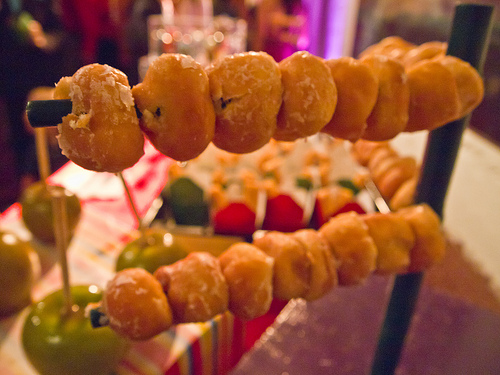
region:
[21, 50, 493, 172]
food on a stick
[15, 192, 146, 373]
green apple on a stick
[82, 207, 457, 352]
donut holes on a pole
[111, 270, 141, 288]
bit of glaze peeling off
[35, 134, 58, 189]
stick sticking out of the apple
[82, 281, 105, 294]
light gleaming on the apple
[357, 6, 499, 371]
skinny black pole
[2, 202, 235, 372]
multicolored striped tablecloth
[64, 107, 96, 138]
bit of donut falling off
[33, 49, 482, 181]
row of eight donut holes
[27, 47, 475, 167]
row of pastries on pole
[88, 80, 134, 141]
glaze coating on pastry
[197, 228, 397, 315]
row of horizontal pastry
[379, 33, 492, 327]
black vertical pole for horizontal poles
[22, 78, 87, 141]
pole end poking through pastry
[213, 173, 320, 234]
red boxes on table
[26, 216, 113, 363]
stick in green apple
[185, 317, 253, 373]
edge of striped tablecloth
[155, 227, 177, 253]
light reflection on apple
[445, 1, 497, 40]
top of black pole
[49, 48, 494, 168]
brown doughnuts on black bar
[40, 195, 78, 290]
brown candy apple stick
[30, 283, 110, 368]
green candied apple sitting on table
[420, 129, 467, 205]
black metal pole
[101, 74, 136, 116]
white glaze on side of doughnut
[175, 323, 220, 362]
striped table cloth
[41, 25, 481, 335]
doughnuts cooling on black pole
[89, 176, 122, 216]
light shining on table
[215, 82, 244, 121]
hole in middle of doughnut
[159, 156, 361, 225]
food sitting on table top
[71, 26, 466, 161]
these are the doughnuts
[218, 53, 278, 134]
the doughnut is brown in color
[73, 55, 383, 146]
the doughnuts are in a line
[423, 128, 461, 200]
this is a pole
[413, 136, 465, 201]
the pole is black in color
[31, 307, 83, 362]
this is an apple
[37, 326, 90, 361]
the apple is green in color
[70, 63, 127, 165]
the doughnut is creamy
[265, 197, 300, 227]
the container is red in color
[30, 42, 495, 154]
a long food skewer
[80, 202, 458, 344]
a long food skewer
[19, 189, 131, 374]
a green candy apple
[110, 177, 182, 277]
a green candy apple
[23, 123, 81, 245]
a green candy apple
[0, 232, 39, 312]
a green candy apple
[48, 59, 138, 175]
a glazed doughnut hole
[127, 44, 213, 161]
a glazed doughnut hole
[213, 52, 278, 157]
a glazed doughnut hole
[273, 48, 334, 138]
a glazed doughnut hole